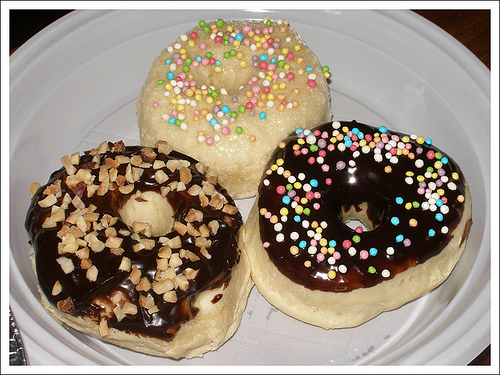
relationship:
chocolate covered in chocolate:
[26, 142, 241, 342] [26, 142, 241, 342]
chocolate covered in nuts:
[26, 142, 241, 342] [29, 138, 238, 341]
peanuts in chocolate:
[26, 138, 237, 340] [26, 142, 241, 342]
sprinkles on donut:
[177, 30, 301, 132] [137, 16, 336, 200]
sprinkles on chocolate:
[283, 140, 423, 248] [259, 119, 464, 294]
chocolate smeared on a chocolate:
[26, 142, 241, 342] [26, 142, 241, 342]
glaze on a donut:
[158, 35, 287, 141] [137, 16, 336, 200]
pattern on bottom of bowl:
[230, 302, 365, 364] [11, 12, 497, 368]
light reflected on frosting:
[342, 165, 363, 189] [261, 118, 469, 296]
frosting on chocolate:
[261, 118, 469, 296] [259, 119, 464, 294]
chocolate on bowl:
[26, 142, 241, 342] [11, 12, 497, 368]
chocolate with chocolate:
[26, 142, 241, 342] [26, 142, 241, 342]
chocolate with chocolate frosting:
[259, 119, 464, 294] [306, 155, 409, 251]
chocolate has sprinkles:
[259, 119, 464, 294] [283, 140, 423, 248]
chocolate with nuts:
[26, 142, 241, 342] [29, 138, 238, 341]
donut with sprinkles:
[137, 16, 336, 200] [177, 30, 301, 132]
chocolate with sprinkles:
[259, 119, 464, 294] [283, 140, 423, 248]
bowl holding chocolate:
[11, 12, 497, 368] [26, 142, 241, 342]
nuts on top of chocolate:
[29, 138, 238, 341] [26, 142, 241, 342]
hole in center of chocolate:
[116, 190, 176, 236] [26, 142, 241, 342]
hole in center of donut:
[205, 57, 259, 88] [137, 16, 336, 200]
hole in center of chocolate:
[333, 186, 393, 232] [259, 119, 464, 294]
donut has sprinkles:
[137, 16, 336, 200] [177, 30, 301, 132]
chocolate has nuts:
[26, 142, 241, 342] [29, 138, 238, 341]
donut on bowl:
[137, 16, 336, 200] [11, 12, 497, 368]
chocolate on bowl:
[259, 119, 464, 294] [11, 12, 497, 368]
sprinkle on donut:
[215, 17, 226, 28] [137, 16, 336, 200]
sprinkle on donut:
[181, 54, 195, 67] [137, 16, 336, 200]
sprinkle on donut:
[234, 121, 245, 137] [137, 16, 336, 200]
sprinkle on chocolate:
[282, 179, 295, 193] [259, 119, 464, 294]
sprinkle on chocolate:
[351, 231, 362, 244] [259, 119, 464, 294]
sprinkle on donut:
[241, 23, 253, 33] [137, 16, 336, 200]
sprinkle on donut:
[260, 24, 273, 35] [137, 16, 336, 200]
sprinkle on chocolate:
[272, 182, 288, 197] [259, 119, 464, 294]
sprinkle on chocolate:
[303, 189, 316, 202] [259, 119, 464, 294]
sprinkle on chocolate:
[340, 236, 354, 252] [259, 119, 464, 294]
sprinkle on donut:
[166, 70, 180, 81] [137, 16, 336, 200]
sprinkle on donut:
[165, 114, 178, 126] [137, 16, 336, 200]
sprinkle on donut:
[256, 110, 270, 121] [137, 16, 336, 200]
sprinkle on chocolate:
[427, 227, 437, 238] [259, 119, 464, 294]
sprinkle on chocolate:
[434, 211, 445, 225] [259, 119, 464, 294]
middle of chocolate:
[119, 185, 178, 239] [26, 142, 241, 342]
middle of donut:
[208, 60, 256, 91] [137, 16, 336, 200]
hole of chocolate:
[333, 186, 393, 232] [259, 119, 464, 294]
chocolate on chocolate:
[26, 142, 241, 342] [26, 142, 241, 342]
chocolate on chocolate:
[259, 119, 464, 294] [259, 119, 464, 294]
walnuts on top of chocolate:
[64, 190, 196, 301] [26, 142, 241, 342]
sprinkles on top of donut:
[177, 30, 301, 132] [137, 16, 336, 200]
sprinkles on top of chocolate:
[283, 140, 423, 248] [259, 119, 464, 294]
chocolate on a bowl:
[26, 142, 241, 342] [11, 12, 497, 368]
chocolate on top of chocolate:
[26, 142, 241, 342] [26, 142, 241, 342]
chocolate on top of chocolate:
[259, 119, 464, 294] [259, 119, 464, 294]